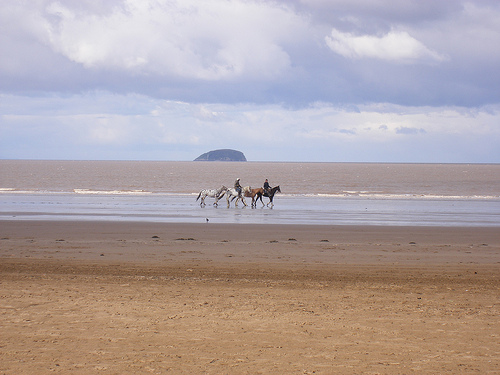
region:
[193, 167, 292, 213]
horses in the stream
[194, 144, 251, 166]
rock behind the desert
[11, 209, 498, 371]
sand on the beach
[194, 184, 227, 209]
the horse is white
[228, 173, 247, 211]
person riding a white horse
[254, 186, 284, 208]
the horse is brown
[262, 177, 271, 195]
person riding the horse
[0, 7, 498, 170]
grey clouds in the sky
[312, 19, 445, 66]
white clouds in front of the grey clouds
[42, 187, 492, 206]
waves splashing on beach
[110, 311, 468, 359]
sand on the beach.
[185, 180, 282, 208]
Three horses walking on the beach.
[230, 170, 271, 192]
Two people riding on horses.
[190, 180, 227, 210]
A horse without a rider.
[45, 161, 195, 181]
The water is light brown.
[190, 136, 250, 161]
A small island in the distance.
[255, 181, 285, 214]
The horse is dark brown.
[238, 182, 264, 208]
The horse is light brown.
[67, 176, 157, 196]
A small wave on the water.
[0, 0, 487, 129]
Clouds in the sky.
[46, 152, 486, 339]
horses running down beach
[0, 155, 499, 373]
low tide on beach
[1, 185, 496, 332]
wet sand on beach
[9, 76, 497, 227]
two people riding horses down beach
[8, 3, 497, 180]
rolling clouds in sky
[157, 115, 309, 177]
large boulder in water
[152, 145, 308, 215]
two men wearing blue jeans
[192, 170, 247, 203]
man wearing white hat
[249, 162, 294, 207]
man wearing black hat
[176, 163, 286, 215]
one man looking back at another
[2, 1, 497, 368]
A remote beach landscape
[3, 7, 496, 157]
dark clouds in the sky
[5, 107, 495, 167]
A blue horizon meets the water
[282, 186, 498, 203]
small waves on the shore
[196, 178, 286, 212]
two men riding horses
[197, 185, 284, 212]
There are four horses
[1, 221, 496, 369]
Brown sand on the ground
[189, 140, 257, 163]
Very large rock in the water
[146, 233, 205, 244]
scattered rocks on the sand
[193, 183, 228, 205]
one horse is spotted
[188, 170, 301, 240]
horses in the desert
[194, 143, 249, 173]
a rock mountain behind the desert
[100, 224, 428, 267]
small rocks in the sand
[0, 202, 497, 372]
sand in front of the stream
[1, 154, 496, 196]
sand behind the stream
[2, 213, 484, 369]
the sand is brown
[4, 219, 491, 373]
the sand is rocky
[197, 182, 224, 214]
one horse is riderless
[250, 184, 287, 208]
one horse is brown